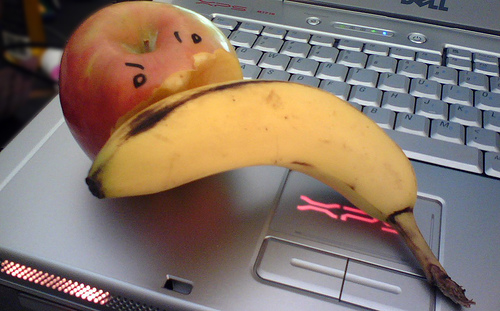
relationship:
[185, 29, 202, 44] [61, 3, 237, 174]
eyes drawn on apple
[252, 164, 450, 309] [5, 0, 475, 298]
touch pad of a laptop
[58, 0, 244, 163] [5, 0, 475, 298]
apple on a laptop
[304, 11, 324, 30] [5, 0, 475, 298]
power buttons on a laptop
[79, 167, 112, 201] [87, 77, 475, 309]
banana end of a banana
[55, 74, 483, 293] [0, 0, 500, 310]
banana on laptop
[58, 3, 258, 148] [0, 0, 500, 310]
apple on laptop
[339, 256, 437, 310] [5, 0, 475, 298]
mouse buttons of a laptop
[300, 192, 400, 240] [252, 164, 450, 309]
pink letters on touch pad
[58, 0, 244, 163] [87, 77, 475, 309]
apple next to banana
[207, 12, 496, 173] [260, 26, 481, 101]
silver keys with black letters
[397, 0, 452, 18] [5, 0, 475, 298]
dell logo on laptop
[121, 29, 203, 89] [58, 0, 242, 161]
eyes drawn on apple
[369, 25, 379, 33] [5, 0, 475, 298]
light on laptop on laptop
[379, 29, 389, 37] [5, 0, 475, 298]
light on laptop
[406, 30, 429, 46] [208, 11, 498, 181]
button behind keyboard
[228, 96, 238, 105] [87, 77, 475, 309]
spot on banana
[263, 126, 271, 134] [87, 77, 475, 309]
spot on banana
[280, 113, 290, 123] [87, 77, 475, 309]
spot on banana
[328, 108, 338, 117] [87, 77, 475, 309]
spot on banana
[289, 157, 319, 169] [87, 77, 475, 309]
spot on banana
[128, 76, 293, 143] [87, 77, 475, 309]
brown streak on banana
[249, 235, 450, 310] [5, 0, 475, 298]
mouse buttons on laptop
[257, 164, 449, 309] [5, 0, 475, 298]
touch pad on laptop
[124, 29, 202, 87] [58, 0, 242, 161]
marks on apple